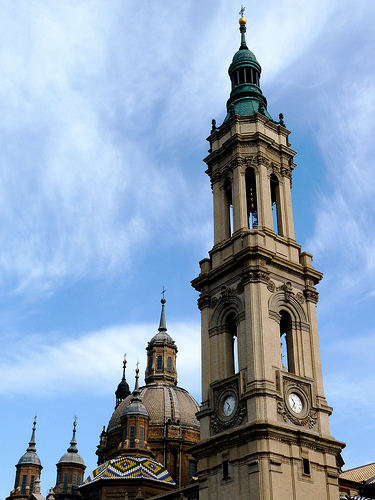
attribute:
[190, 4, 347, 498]
tower — large, stone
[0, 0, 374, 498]
sky — partly cloudy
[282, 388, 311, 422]
clock face — white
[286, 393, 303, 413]
roman numerals — black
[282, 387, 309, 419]
6:55 — time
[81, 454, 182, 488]
tiled turret — black, white, yellow, blue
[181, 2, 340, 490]
stone tower — large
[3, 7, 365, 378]
blue sky — bright blue, sunny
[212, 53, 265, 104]
church roof — decorative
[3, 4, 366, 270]
sky — partly cloudy, blue, white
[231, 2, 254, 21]
cross — small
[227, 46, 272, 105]
cathedral steeple — ornate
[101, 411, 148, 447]
copper steeple — gold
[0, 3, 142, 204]
clouds — white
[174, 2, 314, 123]
cloud — white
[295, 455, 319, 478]
window — small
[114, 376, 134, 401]
roof — black, yellow, blue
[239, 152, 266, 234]
archway — concrete